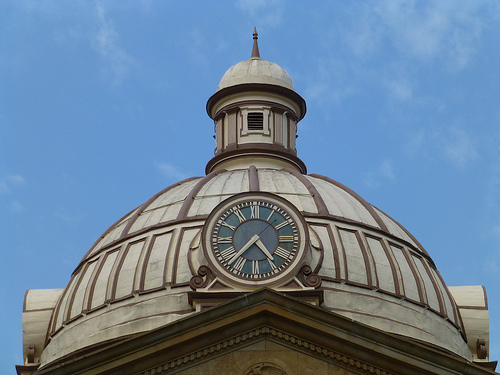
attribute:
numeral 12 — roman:
[248, 205, 261, 219]